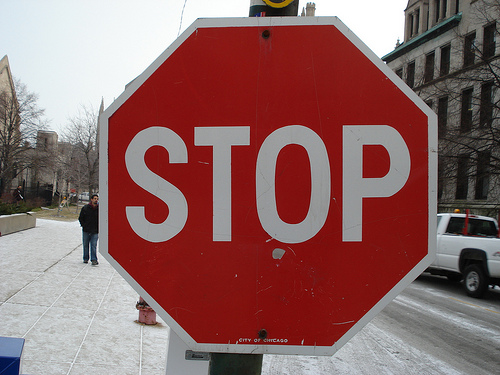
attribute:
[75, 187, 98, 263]
man — walking, waling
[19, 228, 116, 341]
sidewalk — paved, wide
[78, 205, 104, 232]
jacket — black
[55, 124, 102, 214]
tree — bare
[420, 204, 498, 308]
truck — white